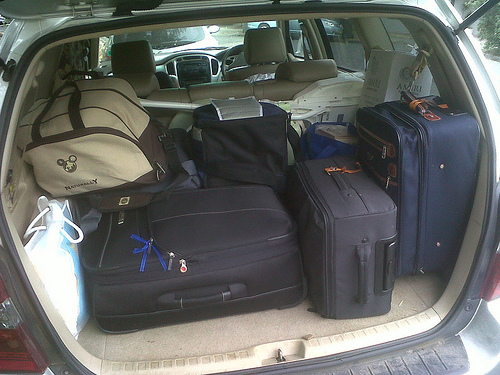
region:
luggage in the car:
[21, 76, 478, 332]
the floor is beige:
[77, 275, 449, 361]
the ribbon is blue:
[130, 233, 165, 271]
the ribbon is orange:
[327, 160, 361, 172]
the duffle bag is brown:
[20, 80, 167, 206]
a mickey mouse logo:
[58, 155, 76, 172]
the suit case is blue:
[356, 97, 476, 279]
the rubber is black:
[255, 333, 467, 373]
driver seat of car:
[110, 40, 178, 91]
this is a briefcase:
[83, 182, 292, 336]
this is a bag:
[5, 81, 160, 206]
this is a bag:
[190, 100, 290, 180]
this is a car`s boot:
[21, 5, 466, 369]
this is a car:
[10, 2, 498, 372]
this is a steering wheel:
[221, 43, 269, 83]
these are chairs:
[108, 30, 335, 97]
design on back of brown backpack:
[47, 149, 92, 179]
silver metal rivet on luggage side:
[434, 156, 454, 176]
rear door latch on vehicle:
[268, 344, 299, 369]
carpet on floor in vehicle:
[146, 326, 228, 355]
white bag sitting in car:
[9, 192, 102, 350]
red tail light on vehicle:
[0, 289, 52, 373]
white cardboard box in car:
[358, 49, 435, 126]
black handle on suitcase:
[322, 160, 352, 197]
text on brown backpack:
[59, 178, 105, 196]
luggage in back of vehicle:
[47, 54, 471, 334]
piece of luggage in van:
[351, 88, 479, 278]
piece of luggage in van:
[288, 155, 398, 318]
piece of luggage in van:
[82, 182, 304, 335]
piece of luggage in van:
[18, 79, 171, 199]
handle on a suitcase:
[351, 240, 376, 304]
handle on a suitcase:
[400, 89, 429, 119]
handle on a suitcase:
[326, 165, 353, 192]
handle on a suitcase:
[158, 285, 238, 312]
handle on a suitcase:
[31, 80, 87, 135]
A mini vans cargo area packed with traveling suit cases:
[17, 70, 483, 337]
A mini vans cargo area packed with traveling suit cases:
[15, 65, 490, 336]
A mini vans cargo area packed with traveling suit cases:
[8, 65, 485, 346]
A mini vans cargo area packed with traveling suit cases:
[5, 70, 487, 350]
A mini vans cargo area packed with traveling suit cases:
[9, 73, 486, 343]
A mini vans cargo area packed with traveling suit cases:
[8, 70, 485, 337]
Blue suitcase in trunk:
[358, 92, 476, 299]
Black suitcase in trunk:
[281, 140, 405, 317]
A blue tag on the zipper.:
[121, 232, 171, 275]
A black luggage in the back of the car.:
[77, 175, 284, 354]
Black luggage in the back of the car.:
[294, 145, 401, 315]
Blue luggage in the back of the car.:
[347, 80, 484, 276]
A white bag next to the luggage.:
[24, 191, 95, 330]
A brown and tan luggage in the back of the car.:
[22, 76, 177, 186]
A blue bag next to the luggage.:
[304, 118, 351, 158]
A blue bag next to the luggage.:
[298, 113, 358, 155]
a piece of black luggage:
[297, 146, 406, 316]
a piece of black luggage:
[82, 185, 304, 331]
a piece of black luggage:
[359, 93, 481, 281]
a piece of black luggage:
[174, 98, 288, 183]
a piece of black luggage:
[140, 137, 202, 189]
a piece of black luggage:
[300, 152, 404, 320]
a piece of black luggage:
[83, 195, 302, 332]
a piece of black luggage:
[360, 91, 477, 286]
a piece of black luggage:
[293, 157, 402, 321]